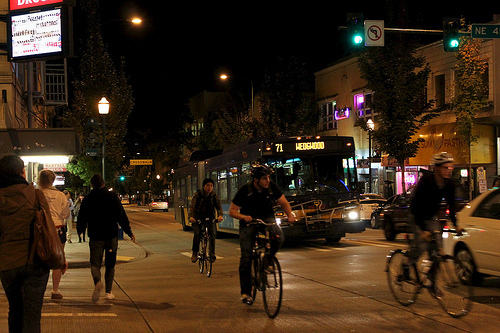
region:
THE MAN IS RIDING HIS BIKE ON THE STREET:
[230, 155, 297, 320]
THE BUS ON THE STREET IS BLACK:
[152, 123, 379, 253]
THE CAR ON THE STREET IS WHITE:
[430, 162, 496, 287]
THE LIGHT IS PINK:
[387, 157, 422, 212]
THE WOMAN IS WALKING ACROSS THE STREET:
[73, 171, 144, 312]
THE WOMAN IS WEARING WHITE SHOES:
[85, 270, 125, 312]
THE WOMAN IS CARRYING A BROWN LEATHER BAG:
[22, 181, 83, 282]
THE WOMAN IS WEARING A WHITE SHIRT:
[40, 173, 76, 234]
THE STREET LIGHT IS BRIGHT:
[70, 90, 125, 141]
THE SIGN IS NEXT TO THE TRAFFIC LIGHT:
[358, 15, 385, 69]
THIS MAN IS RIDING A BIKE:
[227, 150, 300, 316]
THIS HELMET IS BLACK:
[245, 156, 271, 177]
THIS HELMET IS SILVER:
[426, 147, 452, 167]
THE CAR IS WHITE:
[430, 171, 497, 291]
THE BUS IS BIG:
[155, 125, 377, 255]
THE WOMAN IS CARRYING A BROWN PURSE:
[20, 183, 67, 271]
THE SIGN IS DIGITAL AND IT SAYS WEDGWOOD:
[282, 132, 343, 154]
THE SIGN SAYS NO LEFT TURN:
[360, 20, 383, 46]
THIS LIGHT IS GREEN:
[446, 36, 461, 50]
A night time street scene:
[0, 0, 498, 332]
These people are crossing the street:
[0, 150, 140, 331]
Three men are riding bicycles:
[185, 148, 476, 328]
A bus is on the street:
[169, 130, 369, 247]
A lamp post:
[93, 95, 114, 178]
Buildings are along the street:
[176, 32, 498, 225]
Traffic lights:
[343, 7, 463, 54]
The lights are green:
[343, 30, 461, 50]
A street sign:
[363, 17, 387, 47]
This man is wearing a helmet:
[246, 159, 275, 190]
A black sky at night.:
[5, 3, 490, 145]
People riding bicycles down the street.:
[185, 146, 482, 331]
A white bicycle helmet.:
[430, 149, 454, 167]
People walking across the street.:
[0, 143, 144, 332]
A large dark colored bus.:
[167, 130, 364, 254]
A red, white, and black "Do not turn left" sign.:
[362, 20, 386, 46]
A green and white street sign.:
[469, 22, 498, 39]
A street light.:
[94, 93, 111, 178]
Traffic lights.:
[352, 18, 461, 52]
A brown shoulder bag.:
[26, 188, 67, 283]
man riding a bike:
[221, 155, 317, 327]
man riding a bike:
[169, 160, 236, 292]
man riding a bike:
[380, 139, 480, 325]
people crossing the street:
[2, 139, 137, 326]